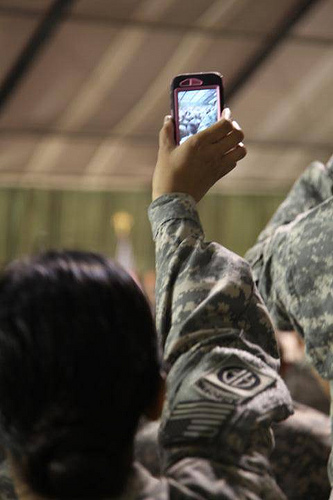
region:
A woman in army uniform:
[15, 176, 286, 498]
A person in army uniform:
[256, 161, 332, 400]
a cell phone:
[162, 65, 238, 168]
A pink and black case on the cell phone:
[166, 68, 235, 175]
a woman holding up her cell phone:
[13, 63, 288, 495]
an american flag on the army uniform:
[164, 382, 235, 449]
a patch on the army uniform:
[191, 333, 261, 411]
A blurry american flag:
[103, 213, 147, 281]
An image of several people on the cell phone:
[175, 104, 218, 141]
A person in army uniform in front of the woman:
[133, 359, 331, 487]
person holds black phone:
[159, 82, 236, 173]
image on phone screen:
[178, 98, 211, 147]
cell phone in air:
[168, 76, 220, 160]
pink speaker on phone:
[182, 75, 205, 84]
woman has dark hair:
[3, 242, 149, 451]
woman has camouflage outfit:
[153, 209, 256, 476]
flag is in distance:
[103, 209, 153, 296]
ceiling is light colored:
[32, 2, 174, 184]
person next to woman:
[266, 171, 330, 348]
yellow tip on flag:
[111, 212, 134, 241]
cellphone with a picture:
[152, 60, 247, 157]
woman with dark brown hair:
[7, 183, 175, 476]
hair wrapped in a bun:
[11, 377, 122, 484]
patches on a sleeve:
[141, 339, 293, 461]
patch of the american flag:
[141, 386, 241, 443]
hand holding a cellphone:
[145, 90, 265, 224]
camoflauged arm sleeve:
[127, 187, 299, 474]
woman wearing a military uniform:
[12, 114, 312, 489]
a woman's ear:
[112, 333, 178, 432]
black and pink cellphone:
[153, 61, 255, 179]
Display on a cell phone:
[174, 90, 219, 142]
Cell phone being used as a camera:
[164, 59, 238, 171]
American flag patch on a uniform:
[162, 400, 239, 447]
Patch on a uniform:
[192, 347, 279, 403]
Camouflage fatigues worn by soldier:
[164, 226, 219, 340]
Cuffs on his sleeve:
[140, 191, 209, 239]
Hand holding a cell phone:
[139, 107, 251, 211]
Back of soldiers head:
[3, 247, 170, 498]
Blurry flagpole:
[104, 208, 147, 265]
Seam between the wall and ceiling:
[18, 166, 120, 210]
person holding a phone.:
[143, 63, 251, 203]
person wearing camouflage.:
[141, 187, 292, 473]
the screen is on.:
[174, 87, 220, 140]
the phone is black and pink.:
[163, 65, 225, 143]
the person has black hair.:
[2, 244, 163, 495]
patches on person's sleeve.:
[160, 347, 280, 445]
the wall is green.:
[0, 181, 274, 277]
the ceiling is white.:
[1, 1, 326, 200]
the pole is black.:
[0, 0, 81, 112]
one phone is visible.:
[164, 70, 229, 135]